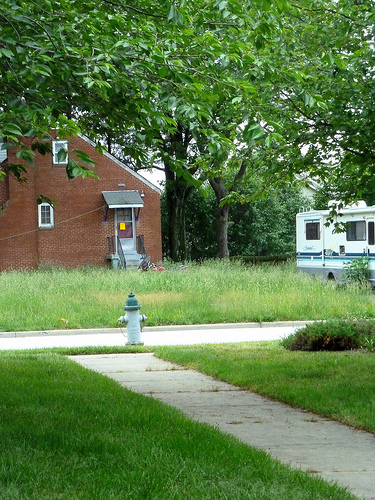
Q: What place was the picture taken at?
A: It was taken at the yard.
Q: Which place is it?
A: It is a yard.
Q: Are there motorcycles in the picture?
A: Yes, there is a motorcycle.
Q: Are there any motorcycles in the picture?
A: Yes, there is a motorcycle.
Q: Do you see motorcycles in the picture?
A: Yes, there is a motorcycle.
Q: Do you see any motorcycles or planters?
A: Yes, there is a motorcycle.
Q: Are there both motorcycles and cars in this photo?
A: No, there is a motorcycle but no cars.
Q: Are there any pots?
A: No, there are no pots.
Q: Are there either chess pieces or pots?
A: No, there are no pots or chess pieces.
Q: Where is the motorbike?
A: The motorbike is in the grass.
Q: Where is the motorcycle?
A: The motorbike is in the grass.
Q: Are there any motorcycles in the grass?
A: Yes, there is a motorcycle in the grass.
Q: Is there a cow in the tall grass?
A: No, there is a motorcycle in the grass.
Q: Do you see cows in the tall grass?
A: No, there is a motorcycle in the grass.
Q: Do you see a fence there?
A: No, there are no fences.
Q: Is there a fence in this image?
A: No, there are no fences.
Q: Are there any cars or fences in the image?
A: No, there are no fences or cars.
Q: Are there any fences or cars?
A: No, there are no cars or fences.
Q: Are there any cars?
A: No, there are no cars.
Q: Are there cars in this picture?
A: No, there are no cars.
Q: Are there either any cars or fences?
A: No, there are no cars or fences.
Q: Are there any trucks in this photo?
A: No, there are no trucks.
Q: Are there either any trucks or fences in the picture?
A: No, there are no trucks or fences.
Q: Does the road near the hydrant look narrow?
A: Yes, the road is narrow.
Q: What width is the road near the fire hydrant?
A: The road is narrow.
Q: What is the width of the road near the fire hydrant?
A: The road is narrow.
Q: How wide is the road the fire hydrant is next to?
A: The road is narrow.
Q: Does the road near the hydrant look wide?
A: No, the road is narrow.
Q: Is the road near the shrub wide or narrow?
A: The road is narrow.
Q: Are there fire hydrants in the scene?
A: Yes, there is a fire hydrant.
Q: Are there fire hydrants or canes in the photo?
A: Yes, there is a fire hydrant.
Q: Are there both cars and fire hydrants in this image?
A: No, there is a fire hydrant but no cars.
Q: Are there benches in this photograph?
A: No, there are no benches.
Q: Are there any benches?
A: No, there are no benches.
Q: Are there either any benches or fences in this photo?
A: No, there are no benches or fences.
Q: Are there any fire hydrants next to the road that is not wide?
A: Yes, there is a fire hydrant next to the road.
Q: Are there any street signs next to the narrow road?
A: No, there is a fire hydrant next to the road.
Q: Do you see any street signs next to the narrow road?
A: No, there is a fire hydrant next to the road.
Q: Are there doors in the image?
A: Yes, there is a door.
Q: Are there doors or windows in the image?
A: Yes, there is a door.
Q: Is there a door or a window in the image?
A: Yes, there is a door.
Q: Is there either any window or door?
A: Yes, there is a door.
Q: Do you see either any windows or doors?
A: Yes, there is a door.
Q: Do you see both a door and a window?
A: Yes, there are both a door and a window.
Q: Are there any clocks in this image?
A: No, there are no clocks.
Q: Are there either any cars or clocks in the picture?
A: No, there are no clocks or cars.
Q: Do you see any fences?
A: No, there are no fences.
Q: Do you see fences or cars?
A: No, there are no fences or cars.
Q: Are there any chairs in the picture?
A: No, there are no chairs.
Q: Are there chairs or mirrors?
A: No, there are no chairs or mirrors.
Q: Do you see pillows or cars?
A: No, there are no cars or pillows.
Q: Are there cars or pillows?
A: No, there are no cars or pillows.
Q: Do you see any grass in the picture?
A: Yes, there is grass.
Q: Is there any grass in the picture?
A: Yes, there is grass.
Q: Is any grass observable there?
A: Yes, there is grass.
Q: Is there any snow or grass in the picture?
A: Yes, there is grass.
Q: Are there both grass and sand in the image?
A: No, there is grass but no sand.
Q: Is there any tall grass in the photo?
A: Yes, there is tall grass.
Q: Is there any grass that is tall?
A: Yes, there is grass that is tall.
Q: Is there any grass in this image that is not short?
A: Yes, there is tall grass.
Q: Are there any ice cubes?
A: No, there are no ice cubes.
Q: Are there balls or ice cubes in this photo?
A: No, there are no ice cubes or balls.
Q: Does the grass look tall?
A: Yes, the grass is tall.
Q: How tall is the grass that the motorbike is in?
A: The grass is tall.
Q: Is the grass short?
A: No, the grass is tall.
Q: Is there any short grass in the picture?
A: No, there is grass but it is tall.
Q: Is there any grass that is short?
A: No, there is grass but it is tall.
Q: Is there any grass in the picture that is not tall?
A: No, there is grass but it is tall.